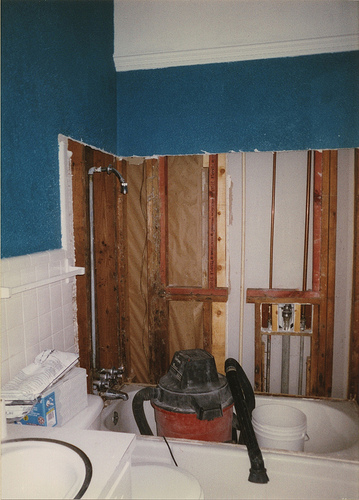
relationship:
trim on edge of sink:
[4, 429, 93, 498] [1, 432, 93, 498]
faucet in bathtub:
[91, 375, 129, 403] [85, 373, 357, 460]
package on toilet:
[0, 349, 88, 427] [53, 394, 205, 497]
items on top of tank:
[17, 335, 118, 452] [79, 389, 110, 443]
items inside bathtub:
[131, 350, 309, 449] [107, 387, 347, 473]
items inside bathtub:
[131, 350, 269, 485] [104, 364, 356, 498]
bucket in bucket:
[248, 399, 309, 460] [248, 399, 309, 460]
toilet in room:
[43, 390, 204, 497] [3, 1, 357, 497]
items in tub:
[131, 350, 269, 485] [85, 363, 345, 445]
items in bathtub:
[131, 350, 269, 485] [96, 377, 356, 498]